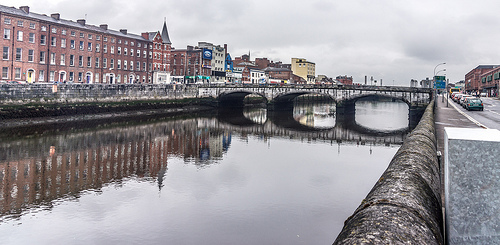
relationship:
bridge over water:
[211, 84, 428, 108] [290, 163, 311, 181]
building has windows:
[4, 9, 211, 77] [77, 33, 123, 80]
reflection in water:
[22, 132, 244, 185] [290, 163, 311, 181]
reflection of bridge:
[22, 132, 244, 185] [211, 84, 428, 108]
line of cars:
[453, 87, 500, 132] [468, 95, 479, 110]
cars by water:
[468, 95, 479, 110] [290, 163, 311, 181]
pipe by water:
[413, 135, 449, 174] [290, 163, 311, 181]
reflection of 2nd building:
[22, 132, 244, 185] [196, 112, 224, 157]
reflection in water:
[184, 115, 235, 171] [290, 163, 311, 181]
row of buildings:
[469, 81, 472, 83] [459, 68, 498, 108]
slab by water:
[455, 135, 490, 193] [290, 163, 311, 181]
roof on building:
[152, 17, 180, 40] [4, 9, 211, 77]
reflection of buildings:
[22, 132, 244, 185] [459, 68, 498, 108]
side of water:
[74, 107, 153, 130] [290, 163, 311, 181]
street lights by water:
[431, 56, 449, 101] [290, 163, 311, 181]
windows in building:
[77, 33, 123, 80] [4, 9, 211, 77]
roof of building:
[152, 17, 180, 40] [4, 9, 211, 77]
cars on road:
[468, 95, 479, 110] [486, 107, 494, 119]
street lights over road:
[431, 56, 449, 101] [486, 107, 494, 119]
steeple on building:
[158, 0, 203, 31] [4, 9, 211, 77]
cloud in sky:
[351, 23, 420, 44] [216, 10, 327, 35]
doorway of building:
[28, 68, 39, 88] [4, 9, 211, 77]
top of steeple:
[161, 11, 170, 24] [158, 0, 203, 31]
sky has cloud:
[216, 10, 327, 35] [351, 23, 420, 44]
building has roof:
[4, 9, 211, 77] [152, 17, 180, 40]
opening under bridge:
[219, 84, 288, 115] [211, 84, 428, 108]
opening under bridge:
[267, 94, 341, 116] [211, 84, 428, 108]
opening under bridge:
[344, 98, 413, 122] [211, 84, 428, 108]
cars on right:
[468, 95, 479, 110] [452, 76, 459, 78]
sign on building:
[203, 48, 211, 59] [174, 50, 211, 79]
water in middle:
[290, 163, 311, 181] [254, 145, 318, 173]